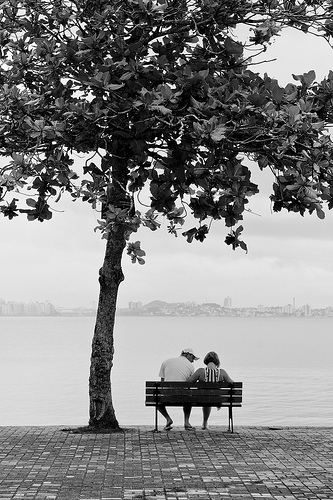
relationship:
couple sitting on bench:
[159, 347, 234, 429] [142, 381, 243, 407]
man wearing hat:
[157, 347, 196, 430] [180, 349, 201, 363]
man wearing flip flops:
[157, 347, 196, 430] [160, 419, 194, 430]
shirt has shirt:
[159, 356, 195, 381] [159, 356, 195, 381]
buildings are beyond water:
[0, 297, 328, 316] [1, 316, 332, 429]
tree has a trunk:
[0, 0, 333, 428] [86, 135, 127, 433]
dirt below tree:
[64, 426, 128, 437] [0, 0, 333, 428]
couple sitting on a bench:
[159, 347, 234, 429] [142, 381, 243, 407]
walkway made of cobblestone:
[4, 429, 333, 498] [3, 426, 332, 496]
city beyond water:
[0, 297, 328, 316] [1, 316, 332, 429]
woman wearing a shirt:
[188, 350, 237, 424] [201, 368, 226, 383]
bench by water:
[142, 381, 243, 407] [1, 316, 332, 429]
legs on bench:
[152, 405, 239, 435] [142, 381, 243, 407]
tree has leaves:
[0, 0, 333, 428] [0, 2, 331, 266]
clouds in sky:
[158, 196, 331, 303] [0, 0, 331, 311]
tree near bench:
[0, 0, 333, 428] [142, 381, 243, 407]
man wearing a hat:
[157, 347, 196, 430] [180, 349, 201, 363]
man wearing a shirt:
[157, 347, 196, 430] [159, 356, 195, 385]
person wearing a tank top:
[188, 350, 237, 424] [199, 363, 227, 388]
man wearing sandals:
[157, 347, 196, 430] [158, 423, 199, 431]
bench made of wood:
[142, 381, 243, 407] [146, 380, 243, 407]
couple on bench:
[159, 347, 234, 429] [142, 381, 243, 407]